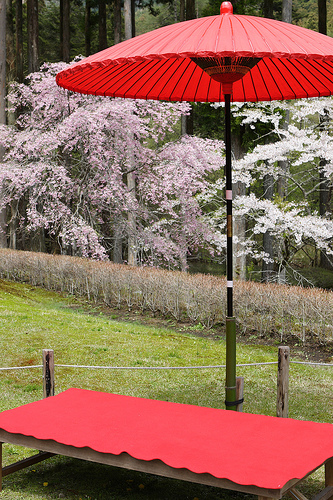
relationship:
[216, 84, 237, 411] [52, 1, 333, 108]
pole has canopy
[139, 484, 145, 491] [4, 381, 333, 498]
flower under stage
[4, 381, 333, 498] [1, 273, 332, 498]
stage on lawn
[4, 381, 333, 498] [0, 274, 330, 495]
stage on grass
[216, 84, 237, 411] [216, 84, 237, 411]
pole has pole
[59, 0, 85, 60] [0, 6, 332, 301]
tree in background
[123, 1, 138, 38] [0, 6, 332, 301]
tree in background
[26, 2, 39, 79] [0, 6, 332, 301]
tree in background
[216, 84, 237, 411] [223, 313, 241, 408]
pole has portion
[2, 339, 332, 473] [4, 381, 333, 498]
barrier around stage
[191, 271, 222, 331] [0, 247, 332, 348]
bush in row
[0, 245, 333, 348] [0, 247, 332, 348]
bush in row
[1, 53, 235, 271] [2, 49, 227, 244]
tree in flowers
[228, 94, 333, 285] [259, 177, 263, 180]
tree in flower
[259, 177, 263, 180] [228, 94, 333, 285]
flower from tree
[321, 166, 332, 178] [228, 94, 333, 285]
flower from tree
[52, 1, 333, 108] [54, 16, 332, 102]
canopy with fabric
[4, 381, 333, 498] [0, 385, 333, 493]
bench covered in covering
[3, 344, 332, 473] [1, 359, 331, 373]
fence made of rope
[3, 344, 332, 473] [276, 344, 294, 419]
fence made of post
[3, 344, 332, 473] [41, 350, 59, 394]
fence made of post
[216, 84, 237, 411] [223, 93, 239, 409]
pole made of metal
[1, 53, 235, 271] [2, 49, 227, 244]
tree in bloom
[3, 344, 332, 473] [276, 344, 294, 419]
fence with post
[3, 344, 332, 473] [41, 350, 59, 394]
fence with post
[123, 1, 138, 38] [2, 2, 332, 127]
tree in forest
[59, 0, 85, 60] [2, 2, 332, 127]
tree in forest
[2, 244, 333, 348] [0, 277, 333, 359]
hedge on edge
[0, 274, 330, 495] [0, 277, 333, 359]
grass has edge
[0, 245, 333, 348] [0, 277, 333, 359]
bush on edge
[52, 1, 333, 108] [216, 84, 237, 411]
canopy on pole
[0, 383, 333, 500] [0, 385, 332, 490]
stage in red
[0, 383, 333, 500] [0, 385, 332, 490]
stage covered in red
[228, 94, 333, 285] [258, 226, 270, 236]
tree has blossom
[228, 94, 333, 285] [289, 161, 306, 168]
tree has blossom